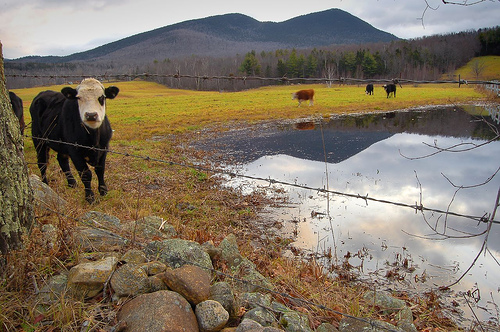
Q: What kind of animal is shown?
A: Cow.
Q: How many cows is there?
A: 1.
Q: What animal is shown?
A: Cow.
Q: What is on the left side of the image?
A: Tree trunk.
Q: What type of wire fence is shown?
A: Barb wire.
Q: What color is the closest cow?
A: Black and white.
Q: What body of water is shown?
A: Pond.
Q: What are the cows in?
A: Pasture.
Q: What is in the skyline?
A: Mountains.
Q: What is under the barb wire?
A: Rocks.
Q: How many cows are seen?
A: Five.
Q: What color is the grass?
A: Green and yellow.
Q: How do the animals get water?
A: From the pond.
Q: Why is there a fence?
A: Keep the animals contained.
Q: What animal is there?
A: Cow.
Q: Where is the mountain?
A: Horizon.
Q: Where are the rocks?
A: Foreground.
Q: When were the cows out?
A: Cloudy day.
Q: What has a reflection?
A: Water.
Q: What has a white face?
A: Closest cow.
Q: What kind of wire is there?
A: Barbed.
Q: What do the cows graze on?
A: Grass.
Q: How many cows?
A: Four.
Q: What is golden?
A: Grass.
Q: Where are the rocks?
A: In the left corner.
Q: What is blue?
A: Sky.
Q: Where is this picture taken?
A: In a field.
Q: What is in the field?
A: Cows.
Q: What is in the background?
A: Mountains.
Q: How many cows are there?
A: Four.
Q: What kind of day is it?
A: Cloudy.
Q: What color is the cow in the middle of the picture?
A: Brown.